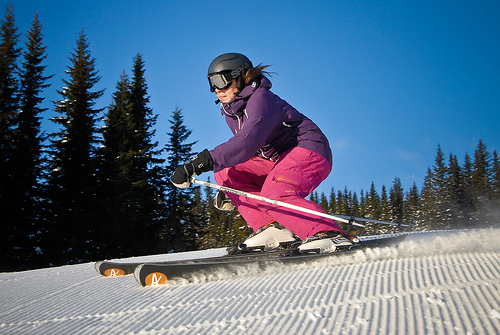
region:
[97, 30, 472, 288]
the girl is skiing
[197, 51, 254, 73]
the girl is wearing a black helmet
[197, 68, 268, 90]
the girl is wearing goggles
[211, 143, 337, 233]
the girl is wearing pink pants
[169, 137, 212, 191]
the girl is wearing black gloves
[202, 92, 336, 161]
the girl is wearing a purple jacket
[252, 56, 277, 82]
the girl has hair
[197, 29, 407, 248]
the girl is holding ski brakes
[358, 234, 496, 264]
the snow is coming off the ground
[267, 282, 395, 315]
the snow is packed tight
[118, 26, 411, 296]
the woman on skis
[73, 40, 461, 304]
the woman is skiing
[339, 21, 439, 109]
the sky is blue and clear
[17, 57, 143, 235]
the tall pine trees in the background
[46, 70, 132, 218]
the trees are green with leaves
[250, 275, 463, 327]
the tracks in the snow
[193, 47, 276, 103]
the helmet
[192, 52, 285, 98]
the helmet is black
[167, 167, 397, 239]
the ski pole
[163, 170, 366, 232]
the ski pole is white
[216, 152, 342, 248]
pink pants on a skier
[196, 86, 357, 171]
a purple coat on a skier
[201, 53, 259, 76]
a grey helmet on a skier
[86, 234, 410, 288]
a pair of snow skis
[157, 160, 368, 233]
a white ski pole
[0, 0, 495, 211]
a deep blue sky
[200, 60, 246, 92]
ski goggles on a skiers face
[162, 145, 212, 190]
a black glove on a skier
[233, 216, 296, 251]
a white ski boot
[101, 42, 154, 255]
dark green pine trees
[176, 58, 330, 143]
the google is black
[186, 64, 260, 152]
the google is black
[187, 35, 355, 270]
the google is black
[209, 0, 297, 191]
the google is black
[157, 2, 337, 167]
the google is black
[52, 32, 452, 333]
a skier in the snow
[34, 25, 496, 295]
a skier bent over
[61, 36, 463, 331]
a skier leaning to the side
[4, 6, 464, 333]
a skier wearing a helmet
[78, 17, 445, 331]
a woman skiing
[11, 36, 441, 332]
a women sking during the day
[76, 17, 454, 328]
a woman wearing a black helmet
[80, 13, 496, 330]
a women wearing a purple jacket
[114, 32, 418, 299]
a women wearing pink pants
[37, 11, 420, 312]
a women outside in the snow